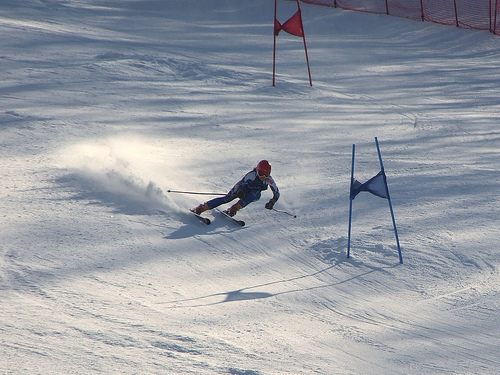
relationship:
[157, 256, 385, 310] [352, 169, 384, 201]
shadow of flag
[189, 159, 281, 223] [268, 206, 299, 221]
man holding pole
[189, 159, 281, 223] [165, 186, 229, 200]
man holding pole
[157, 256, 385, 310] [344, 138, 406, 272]
shadow on stand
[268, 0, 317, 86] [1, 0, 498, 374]
flag in snow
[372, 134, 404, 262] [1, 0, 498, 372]
pole in ice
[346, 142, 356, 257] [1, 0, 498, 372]
pole in ice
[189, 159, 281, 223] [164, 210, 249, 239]
man casting shadow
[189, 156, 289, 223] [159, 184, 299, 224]
man holding pole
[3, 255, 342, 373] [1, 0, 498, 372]
sunshine on ice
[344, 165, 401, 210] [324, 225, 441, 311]
flag on snow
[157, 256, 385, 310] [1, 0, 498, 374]
shadow in snow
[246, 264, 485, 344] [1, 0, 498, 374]
prints in snow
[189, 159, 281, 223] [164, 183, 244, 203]
man carrying pole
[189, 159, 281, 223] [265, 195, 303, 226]
man carrying pole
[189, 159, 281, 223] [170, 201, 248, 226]
man using skis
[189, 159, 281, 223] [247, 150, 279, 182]
man wearing helmet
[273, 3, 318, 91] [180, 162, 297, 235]
flag tells skiier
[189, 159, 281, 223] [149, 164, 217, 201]
man hold poles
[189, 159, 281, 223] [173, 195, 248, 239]
man on skiis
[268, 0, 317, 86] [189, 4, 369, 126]
flag on ice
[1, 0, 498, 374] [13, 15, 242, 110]
snow has nice view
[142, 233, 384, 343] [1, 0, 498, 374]
shadow on snow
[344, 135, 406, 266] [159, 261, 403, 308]
flag casting shadow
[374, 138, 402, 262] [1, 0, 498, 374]
stick stuck in snow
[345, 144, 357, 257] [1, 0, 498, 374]
stick stuck in snow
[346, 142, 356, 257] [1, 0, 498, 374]
pole stuck in snow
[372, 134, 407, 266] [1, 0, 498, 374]
pole stuck in snow